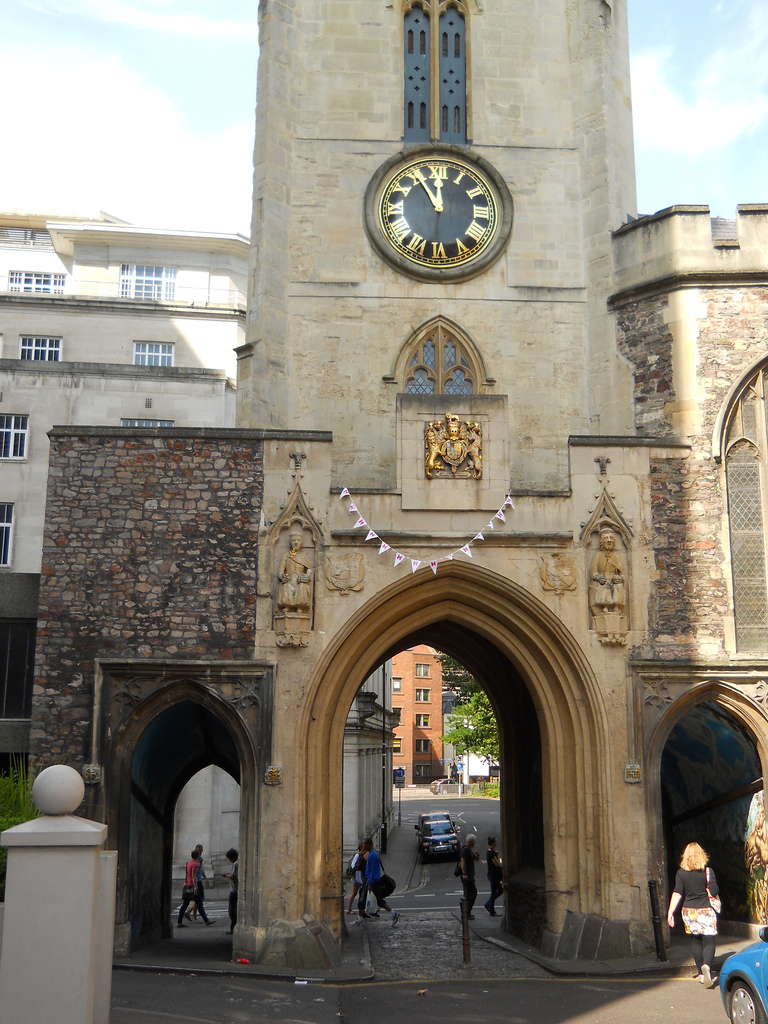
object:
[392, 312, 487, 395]
arch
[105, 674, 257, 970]
arch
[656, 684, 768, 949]
arch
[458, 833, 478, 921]
people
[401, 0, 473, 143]
window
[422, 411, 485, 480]
design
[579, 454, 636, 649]
design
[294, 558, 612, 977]
arch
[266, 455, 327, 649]
design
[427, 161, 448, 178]
roman numeral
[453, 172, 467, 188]
roman numeral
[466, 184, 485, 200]
roman numeral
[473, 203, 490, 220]
roman numeral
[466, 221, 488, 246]
roman numeral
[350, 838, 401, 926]
person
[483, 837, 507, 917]
person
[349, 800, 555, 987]
street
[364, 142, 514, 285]
clock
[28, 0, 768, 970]
building